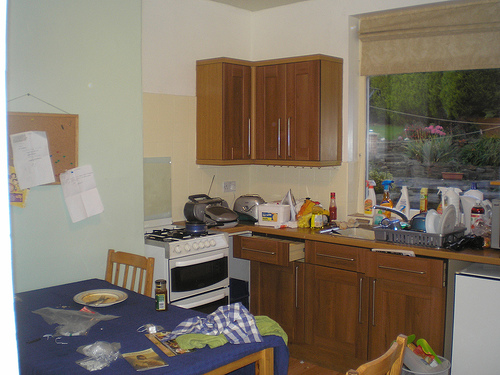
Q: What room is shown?
A: Kitchen.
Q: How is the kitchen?
A: Messy.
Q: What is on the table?
A: Tablecloth.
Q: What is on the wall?
A: Bulletin board.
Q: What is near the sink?
A: Window.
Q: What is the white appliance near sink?
A: Dishwasher.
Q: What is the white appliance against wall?
A: Oven.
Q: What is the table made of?
A: Wood.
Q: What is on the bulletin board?
A: Papers.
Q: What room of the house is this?
A: Kitchen.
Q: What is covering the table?
A: Blue tablecloth.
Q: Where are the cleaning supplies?
A: Behind the sink.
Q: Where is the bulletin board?
A: On the wall above the table.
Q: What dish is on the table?
A: Plate.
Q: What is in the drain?
A: Clean dishes.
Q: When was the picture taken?
A: Evening.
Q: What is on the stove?
A: Pot.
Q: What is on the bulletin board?
A: Papers.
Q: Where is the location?
A: Kitchen.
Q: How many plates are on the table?
A: One.